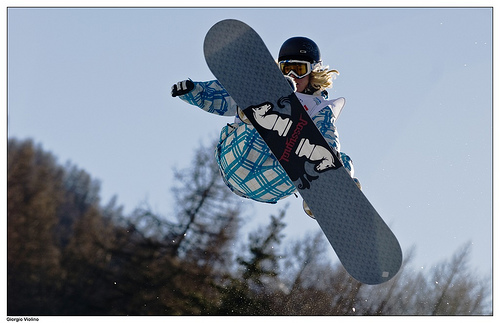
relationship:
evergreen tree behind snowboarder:
[16, 141, 54, 313] [172, 32, 356, 207]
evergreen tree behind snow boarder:
[0, 141, 54, 313] [170, 35, 360, 219]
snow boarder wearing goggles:
[170, 33, 365, 217] [278, 58, 317, 79]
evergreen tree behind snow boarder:
[0, 141, 54, 313] [162, 19, 385, 236]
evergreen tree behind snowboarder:
[0, 141, 54, 313] [172, 32, 356, 207]